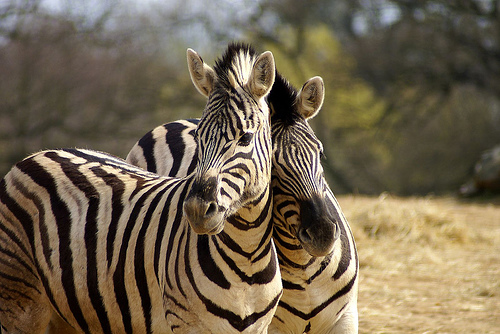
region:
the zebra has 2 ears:
[180, 49, 286, 113]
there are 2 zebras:
[166, 61, 338, 263]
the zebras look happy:
[143, 58, 371, 318]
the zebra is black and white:
[64, 58, 271, 268]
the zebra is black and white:
[271, 120, 358, 307]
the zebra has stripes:
[158, 98, 258, 302]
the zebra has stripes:
[282, 130, 338, 302]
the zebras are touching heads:
[161, 48, 353, 289]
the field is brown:
[393, 203, 464, 299]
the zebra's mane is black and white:
[221, 36, 262, 86]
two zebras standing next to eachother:
[7, 41, 362, 331]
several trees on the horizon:
[0, 5, 495, 207]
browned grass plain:
[332, 197, 497, 328]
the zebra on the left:
[5, 51, 280, 328]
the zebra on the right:
[127, 70, 353, 330]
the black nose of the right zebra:
[305, 196, 335, 251]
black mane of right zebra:
[272, 77, 297, 122]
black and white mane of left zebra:
[213, 49, 252, 89]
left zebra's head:
[178, 48, 275, 233]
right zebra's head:
[270, 76, 340, 253]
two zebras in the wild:
[15, 18, 469, 320]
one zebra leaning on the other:
[33, 48, 399, 314]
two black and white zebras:
[17, 43, 354, 323]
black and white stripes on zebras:
[35, 182, 137, 302]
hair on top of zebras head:
[210, 30, 259, 99]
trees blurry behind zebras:
[10, 15, 485, 165]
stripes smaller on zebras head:
[282, 129, 312, 191]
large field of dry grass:
[370, 187, 485, 327]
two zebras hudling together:
[2, 35, 367, 332]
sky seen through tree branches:
[46, 2, 433, 54]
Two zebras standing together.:
[2, 35, 373, 329]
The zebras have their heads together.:
[166, 38, 351, 261]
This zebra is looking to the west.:
[170, 38, 274, 237]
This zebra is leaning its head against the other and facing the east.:
[261, 66, 355, 270]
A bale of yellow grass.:
[367, 196, 457, 248]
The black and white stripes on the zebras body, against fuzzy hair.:
[9, 141, 129, 332]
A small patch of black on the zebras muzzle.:
[184, 171, 220, 196]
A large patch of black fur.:
[296, 193, 335, 229]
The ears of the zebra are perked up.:
[176, 39, 283, 99]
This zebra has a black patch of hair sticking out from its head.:
[271, 64, 294, 126]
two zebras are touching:
[103, 11, 404, 283]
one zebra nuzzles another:
[139, 3, 391, 260]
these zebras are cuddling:
[106, 8, 413, 298]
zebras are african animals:
[123, 20, 464, 298]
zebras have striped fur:
[146, 8, 388, 281]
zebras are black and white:
[147, 23, 425, 293]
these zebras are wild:
[142, 34, 401, 301]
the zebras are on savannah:
[34, 13, 489, 264]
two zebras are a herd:
[65, 29, 490, 329]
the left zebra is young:
[85, 3, 479, 287]